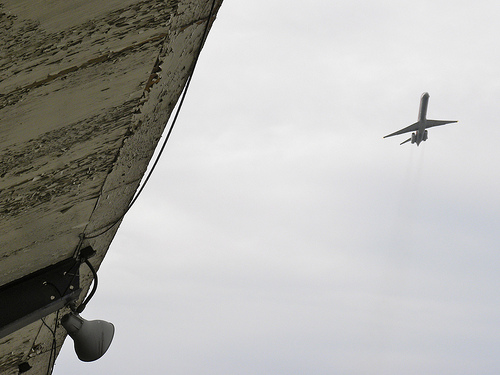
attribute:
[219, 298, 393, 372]
sky — blue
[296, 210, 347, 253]
clouds — white